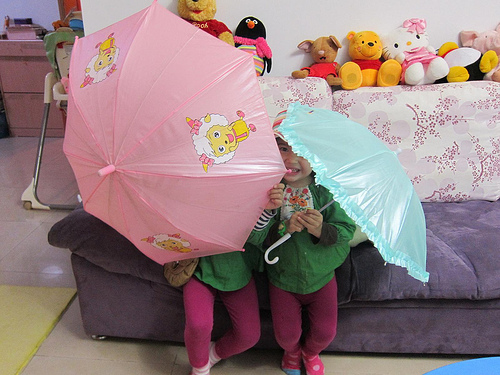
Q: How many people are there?
A: Two.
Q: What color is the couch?
A: Purple.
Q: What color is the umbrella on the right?
A: Blue.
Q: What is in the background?
A: Stuffed animals.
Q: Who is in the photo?
A: Two girls.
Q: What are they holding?
A: Umbrellas.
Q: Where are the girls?
A: On a sofa.